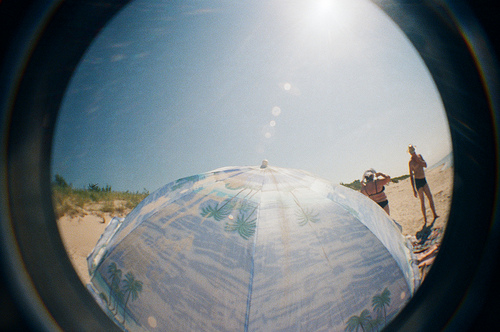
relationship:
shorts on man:
[413, 175, 428, 188] [406, 142, 441, 223]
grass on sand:
[50, 172, 150, 217] [60, 216, 107, 278]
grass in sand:
[67, 188, 92, 217] [52, 200, 134, 275]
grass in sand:
[50, 172, 150, 217] [58, 161, 438, 297]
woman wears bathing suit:
[358, 167, 393, 215] [362, 181, 389, 208]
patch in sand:
[45, 187, 146, 217] [58, 211, 98, 241]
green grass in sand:
[345, 180, 363, 195] [389, 185, 435, 271]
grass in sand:
[384, 171, 412, 186] [59, 155, 461, 324]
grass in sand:
[50, 172, 150, 217] [63, 217, 100, 242]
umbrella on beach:
[86, 159, 421, 329] [50, 164, 454, 287]